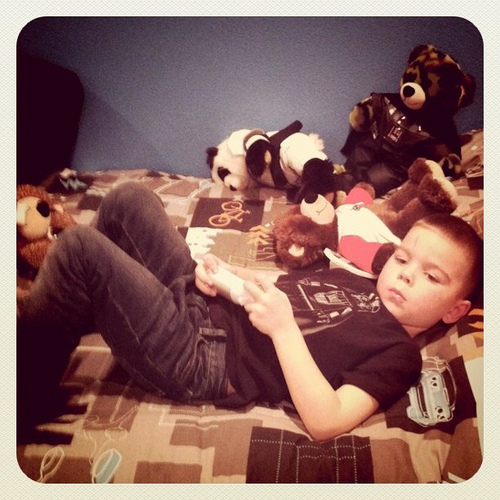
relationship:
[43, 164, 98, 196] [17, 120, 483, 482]
football on bed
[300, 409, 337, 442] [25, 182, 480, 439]
elbow on boy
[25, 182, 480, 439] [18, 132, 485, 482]
boy on bedspread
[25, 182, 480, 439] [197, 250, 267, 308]
boy holding remote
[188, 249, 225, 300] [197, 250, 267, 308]
hand holding remote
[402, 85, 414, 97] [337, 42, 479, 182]
nose on bear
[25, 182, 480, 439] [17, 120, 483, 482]
boy lying on bed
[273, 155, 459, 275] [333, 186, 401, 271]
bear wearing shirt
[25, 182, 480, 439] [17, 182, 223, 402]
boy wearing pant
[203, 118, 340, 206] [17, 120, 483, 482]
bear in bed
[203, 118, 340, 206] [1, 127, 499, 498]
bear in bed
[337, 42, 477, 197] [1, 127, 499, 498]
bear in bed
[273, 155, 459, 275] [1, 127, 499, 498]
bear in bed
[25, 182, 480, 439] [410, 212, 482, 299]
boy has brown hair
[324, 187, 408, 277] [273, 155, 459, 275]
shirt on bear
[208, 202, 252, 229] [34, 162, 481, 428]
bicycle drawing on bed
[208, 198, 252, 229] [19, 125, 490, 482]
bicycle on bedspread